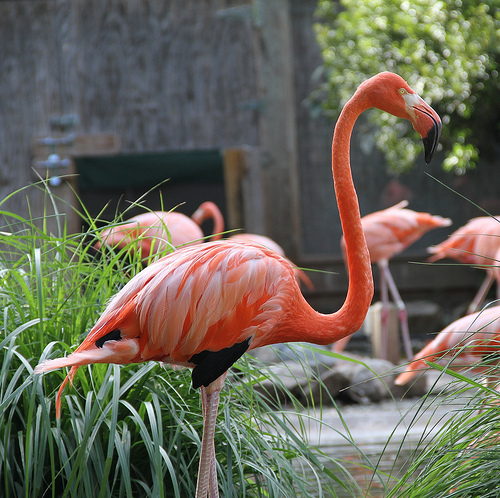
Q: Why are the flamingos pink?
A: Pink food.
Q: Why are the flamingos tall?
A: Long legs.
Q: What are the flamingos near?
A: Water.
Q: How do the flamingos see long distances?
A: Long necks.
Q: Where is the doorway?
A: Behind the flamingos.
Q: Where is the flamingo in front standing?
A: In tall plants.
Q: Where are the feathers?
A: On the bird's side.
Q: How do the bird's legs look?
A: Long and thin.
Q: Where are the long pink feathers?
A: On the bird's tail.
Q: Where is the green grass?
A: Next to the bird.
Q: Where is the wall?
A: Behind the bird.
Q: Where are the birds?
A: In a zoo.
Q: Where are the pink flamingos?
A: In a zoo.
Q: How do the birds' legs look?
A: Long.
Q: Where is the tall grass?
A: Behind the bird.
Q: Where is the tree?
A: Behind the flamingos.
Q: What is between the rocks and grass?
A: Water.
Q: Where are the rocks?
A: Edge of the water.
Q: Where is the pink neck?
A: On the flamingo.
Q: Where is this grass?
A: Behind the flamingo.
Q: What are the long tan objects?
A: Flamingo legs.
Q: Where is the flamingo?
A: Zoo enclosure.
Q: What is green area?
A: Plants around water.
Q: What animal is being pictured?
A: Flamingo.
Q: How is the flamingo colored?
A: Light red, white, and black.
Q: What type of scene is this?
A: Zoo scene.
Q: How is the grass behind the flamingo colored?
A: Green.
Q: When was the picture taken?
A: Daytime.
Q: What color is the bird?
A: Pink.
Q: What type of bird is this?
A: Flamingo.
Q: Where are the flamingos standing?
A: By water.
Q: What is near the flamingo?
A: A bush.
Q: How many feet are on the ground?
A: Two.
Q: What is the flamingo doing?
A: Standing.